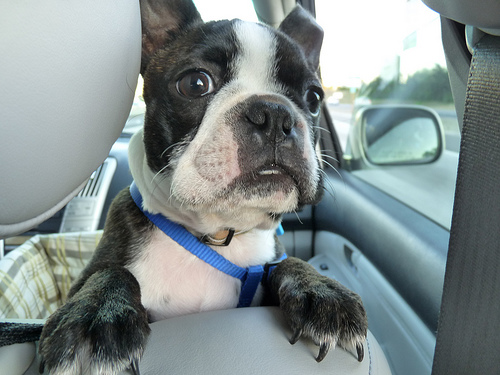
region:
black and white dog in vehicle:
[102, 5, 422, 343]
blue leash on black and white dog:
[104, 14, 362, 358]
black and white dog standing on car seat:
[85, 22, 330, 369]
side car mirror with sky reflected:
[337, 77, 449, 222]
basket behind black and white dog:
[15, 204, 182, 372]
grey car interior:
[8, 7, 455, 361]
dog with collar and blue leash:
[95, 127, 339, 272]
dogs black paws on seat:
[50, 240, 471, 372]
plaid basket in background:
[12, 204, 167, 374]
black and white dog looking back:
[127, 27, 424, 361]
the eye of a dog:
[168, 65, 217, 98]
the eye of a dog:
[296, 82, 325, 117]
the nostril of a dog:
[241, 105, 271, 135]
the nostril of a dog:
[278, 109, 295, 137]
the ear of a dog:
[139, 1, 198, 63]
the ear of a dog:
[281, 3, 327, 68]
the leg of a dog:
[263, 256, 373, 368]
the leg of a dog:
[42, 284, 151, 374]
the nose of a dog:
[238, 95, 295, 154]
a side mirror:
[343, 95, 443, 170]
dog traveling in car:
[52, 4, 423, 366]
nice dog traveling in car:
[45, 0, 400, 362]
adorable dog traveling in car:
[43, 3, 390, 357]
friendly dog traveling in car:
[52, 0, 399, 351]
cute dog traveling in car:
[70, 5, 382, 360]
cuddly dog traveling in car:
[81, 1, 383, 358]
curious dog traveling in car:
[53, 2, 395, 343]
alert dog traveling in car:
[82, 1, 392, 353]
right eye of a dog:
[172, 54, 217, 105]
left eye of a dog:
[296, 83, 329, 128]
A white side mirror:
[350, 94, 450, 164]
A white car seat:
[187, 332, 278, 372]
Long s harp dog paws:
[281, 328, 371, 369]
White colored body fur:
[159, 260, 205, 320]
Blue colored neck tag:
[178, 243, 255, 294]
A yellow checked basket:
[19, 267, 64, 304]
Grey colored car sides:
[346, 202, 425, 260]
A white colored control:
[61, 192, 111, 232]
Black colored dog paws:
[239, 89, 304, 156]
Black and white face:
[143, 12, 373, 135]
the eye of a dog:
[173, 59, 227, 110]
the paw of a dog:
[256, 251, 376, 373]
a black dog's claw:
[309, 334, 331, 361]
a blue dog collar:
[123, 177, 299, 307]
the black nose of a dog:
[239, 99, 307, 141]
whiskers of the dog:
[306, 114, 348, 211]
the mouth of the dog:
[228, 154, 313, 197]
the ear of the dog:
[274, 0, 328, 80]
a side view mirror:
[345, 94, 450, 171]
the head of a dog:
[125, 0, 341, 240]